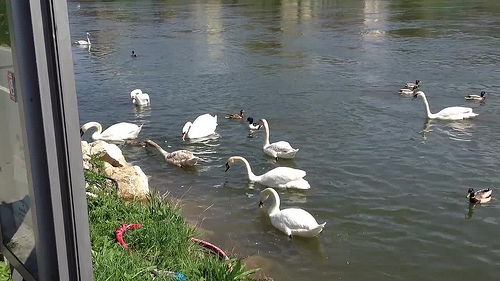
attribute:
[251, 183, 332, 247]
swan — white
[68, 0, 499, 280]
water — calm, lake, reflective, ripply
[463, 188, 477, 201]
head — black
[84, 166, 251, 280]
grass — green, long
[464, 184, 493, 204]
duck — mallard, male, small, swimming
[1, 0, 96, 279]
building — metal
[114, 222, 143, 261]
hose — red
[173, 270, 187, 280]
object — blue, pink